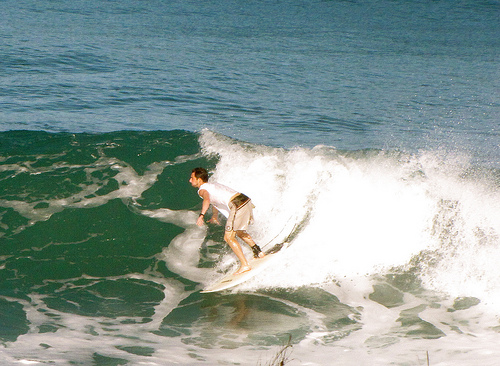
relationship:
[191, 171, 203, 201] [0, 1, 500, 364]
head in water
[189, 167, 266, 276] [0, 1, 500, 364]
man in water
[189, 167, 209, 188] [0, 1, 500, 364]
head in water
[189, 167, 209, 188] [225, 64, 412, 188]
head in water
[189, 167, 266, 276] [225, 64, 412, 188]
man in water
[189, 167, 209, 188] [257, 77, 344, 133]
head in water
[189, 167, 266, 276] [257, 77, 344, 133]
man in water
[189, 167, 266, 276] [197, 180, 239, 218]
man wearing shirt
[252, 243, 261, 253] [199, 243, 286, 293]
ankle wrap onnected to surfboard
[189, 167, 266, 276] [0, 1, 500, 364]
man on water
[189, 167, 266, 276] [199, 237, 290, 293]
man in board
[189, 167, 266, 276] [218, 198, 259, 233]
man in white shorts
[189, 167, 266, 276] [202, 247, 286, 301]
man in surfboard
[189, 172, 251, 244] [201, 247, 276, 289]
man has board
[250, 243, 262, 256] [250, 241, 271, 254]
black cable around ankle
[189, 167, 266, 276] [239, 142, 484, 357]
man facing waves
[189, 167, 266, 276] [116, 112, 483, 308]
man surfing waves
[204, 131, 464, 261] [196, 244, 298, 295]
waves roll surfer